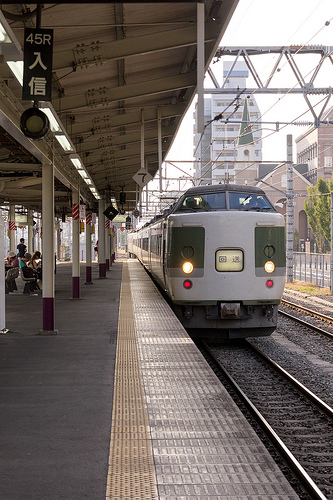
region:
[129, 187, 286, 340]
white train traveling on tracks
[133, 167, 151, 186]
white sign number 7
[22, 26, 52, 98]
black sign with japanese symbols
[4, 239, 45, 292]
crowd of people waiting for train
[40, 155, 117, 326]
white and purpler columns lined up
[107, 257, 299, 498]
long stretch of platform made of bricks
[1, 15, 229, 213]
awning sheltering the platform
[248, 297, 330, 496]
gravel between train tracks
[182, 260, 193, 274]
bright yellow light on the back of train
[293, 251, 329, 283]
small white fencing to the right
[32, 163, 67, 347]
Large metal post in pavement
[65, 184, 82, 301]
Large metal post in pavement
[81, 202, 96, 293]
Large metal post in pavement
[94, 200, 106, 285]
Large metal post in pavement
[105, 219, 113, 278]
Large metal post in pavement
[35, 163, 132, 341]
Large metal post in pavement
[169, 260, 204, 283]
Bright light in a train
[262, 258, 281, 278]
Bright light in a train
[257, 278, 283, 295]
Bright light in a train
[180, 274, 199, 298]
Bright light in a train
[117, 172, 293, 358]
this is a train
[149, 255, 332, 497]
these are the tracks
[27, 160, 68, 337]
this is a post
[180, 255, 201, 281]
this is a headlight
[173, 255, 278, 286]
these are the headlights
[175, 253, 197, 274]
this is the right headlight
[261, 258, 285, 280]
this is the left headlight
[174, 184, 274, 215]
this is a window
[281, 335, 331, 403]
this is the gravel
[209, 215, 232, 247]
this is the color gray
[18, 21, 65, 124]
a black and white sign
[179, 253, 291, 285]
two headlights on train are on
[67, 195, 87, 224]
red patch with white stripes on pole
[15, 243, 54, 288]
people sitting on a bench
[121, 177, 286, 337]
a long train coming down the tracks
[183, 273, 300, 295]
two red lights on front of train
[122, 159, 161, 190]
Black seven on white sign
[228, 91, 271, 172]
a steeple on a building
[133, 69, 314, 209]
wires above the train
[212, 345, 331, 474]
empty track in front of train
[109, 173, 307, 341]
silver train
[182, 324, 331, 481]
train tracks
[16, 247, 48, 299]
people sitting on a bench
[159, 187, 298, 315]
front of a train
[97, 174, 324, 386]
train on its track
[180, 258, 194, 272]
headlight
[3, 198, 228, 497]
train station platform with people waiting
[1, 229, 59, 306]
several people waiting for their train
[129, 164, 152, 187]
number 7 on a sign post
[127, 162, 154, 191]
track location number 7